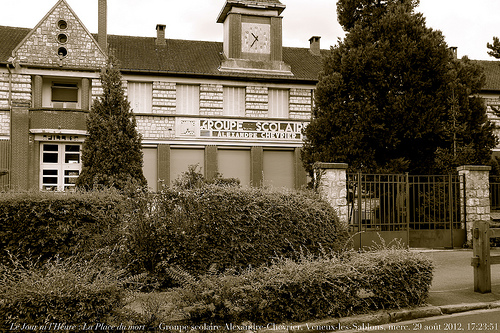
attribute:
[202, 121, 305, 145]
letters — white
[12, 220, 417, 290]
hedge — small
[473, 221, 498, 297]
post — wooden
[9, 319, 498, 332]
writing — white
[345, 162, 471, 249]
gate — metal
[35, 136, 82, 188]
entranceway — white, outlined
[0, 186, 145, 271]
bush — large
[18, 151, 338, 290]
bush — large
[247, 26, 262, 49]
hands — black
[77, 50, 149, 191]
pine — pine tree, narrow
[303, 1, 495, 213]
tree — large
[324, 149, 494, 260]
fence — wooden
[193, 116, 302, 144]
letters — white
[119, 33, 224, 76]
roof — dark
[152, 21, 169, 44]
chimney — small